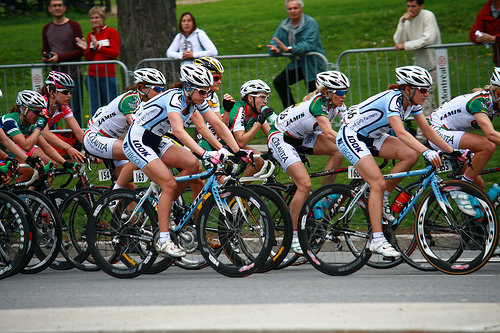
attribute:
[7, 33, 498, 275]
cyclist — human, one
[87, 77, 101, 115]
leg — one, human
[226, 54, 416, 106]
gate — one